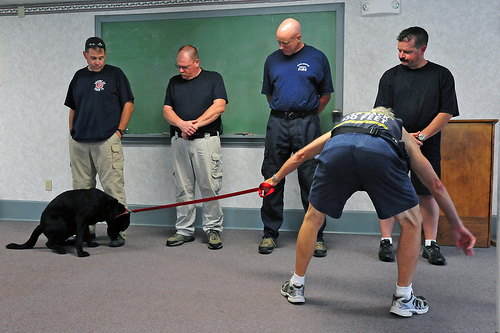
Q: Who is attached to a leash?
A: A dog.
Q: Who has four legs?
A: Dog.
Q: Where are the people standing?
A: In a classroom.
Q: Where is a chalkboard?
A: Behind the men.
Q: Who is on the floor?
A: Black dog.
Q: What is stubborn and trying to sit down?
A: A dog.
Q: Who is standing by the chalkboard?
A: The men.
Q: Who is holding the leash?
A: The person.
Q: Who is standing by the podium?
A: The man.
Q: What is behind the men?
A: The chalkboard.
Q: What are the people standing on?
A: The floor.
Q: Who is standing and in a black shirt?
A: A man.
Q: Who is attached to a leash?
A: A dog.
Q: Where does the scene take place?
A: In a classroom.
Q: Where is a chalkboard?
A: Behind the men.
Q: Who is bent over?
A: Person holding leash.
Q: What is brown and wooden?
A: A podium.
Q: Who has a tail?
A: The dog.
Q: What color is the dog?
A: Black.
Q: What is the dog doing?
A: Sniffing the man's shoes.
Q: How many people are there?
A: Five.